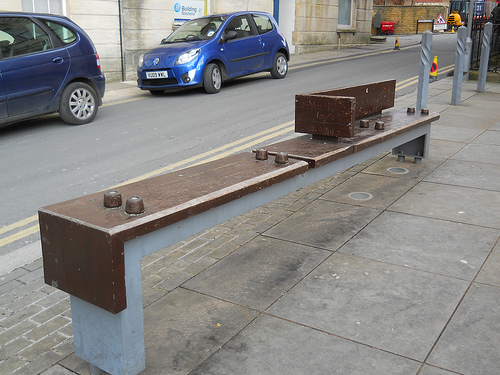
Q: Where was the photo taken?
A: It was taken at the road.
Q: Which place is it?
A: It is a road.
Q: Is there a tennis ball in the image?
A: No, there are no tennis balls.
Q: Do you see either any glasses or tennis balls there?
A: No, there are no tennis balls or glasses.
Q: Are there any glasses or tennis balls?
A: No, there are no tennis balls or glasses.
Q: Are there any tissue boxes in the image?
A: No, there are no tissue boxes.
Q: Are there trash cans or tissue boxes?
A: No, there are no tissue boxes or trash cans.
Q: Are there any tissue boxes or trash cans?
A: No, there are no tissue boxes or trash cans.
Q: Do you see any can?
A: No, there are no cans.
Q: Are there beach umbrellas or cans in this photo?
A: No, there are no cans or beach umbrellas.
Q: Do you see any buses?
A: No, there are no buses.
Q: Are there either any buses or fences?
A: No, there are no buses or fences.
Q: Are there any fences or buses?
A: No, there are no buses or fences.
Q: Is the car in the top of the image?
A: Yes, the car is in the top of the image.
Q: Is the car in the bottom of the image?
A: No, the car is in the top of the image.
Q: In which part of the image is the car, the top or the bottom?
A: The car is in the top of the image.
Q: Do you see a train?
A: No, there are no trains.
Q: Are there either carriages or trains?
A: No, there are no trains or carriages.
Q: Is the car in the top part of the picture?
A: Yes, the car is in the top of the image.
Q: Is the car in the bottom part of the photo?
A: No, the car is in the top of the image.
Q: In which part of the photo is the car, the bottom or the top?
A: The car is in the top of the image.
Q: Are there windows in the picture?
A: Yes, there is a window.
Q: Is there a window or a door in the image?
A: Yes, there is a window.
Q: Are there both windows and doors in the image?
A: Yes, there are both a window and a door.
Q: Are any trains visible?
A: No, there are no trains.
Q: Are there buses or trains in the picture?
A: No, there are no trains or buses.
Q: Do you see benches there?
A: Yes, there is a bench.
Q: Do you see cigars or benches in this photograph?
A: Yes, there is a bench.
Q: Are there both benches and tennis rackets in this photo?
A: No, there is a bench but no rackets.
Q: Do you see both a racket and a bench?
A: No, there is a bench but no rackets.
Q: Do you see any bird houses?
A: No, there are no bird houses.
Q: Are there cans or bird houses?
A: No, there are no bird houses or cans.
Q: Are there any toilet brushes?
A: No, there are no toilet brushes.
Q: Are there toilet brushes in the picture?
A: No, there are no toilet brushes.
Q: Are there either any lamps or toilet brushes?
A: No, there are no toilet brushes or lamps.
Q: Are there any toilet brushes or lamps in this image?
A: No, there are no toilet brushes or lamps.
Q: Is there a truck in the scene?
A: No, there are no trucks.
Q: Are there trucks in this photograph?
A: No, there are no trucks.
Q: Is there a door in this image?
A: Yes, there is a door.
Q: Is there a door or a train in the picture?
A: Yes, there is a door.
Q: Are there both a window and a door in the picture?
A: Yes, there are both a door and a window.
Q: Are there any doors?
A: Yes, there is a door.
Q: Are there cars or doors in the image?
A: Yes, there is a door.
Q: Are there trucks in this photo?
A: No, there are no trucks.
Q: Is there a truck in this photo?
A: No, there are no trucks.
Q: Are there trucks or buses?
A: No, there are no trucks or buses.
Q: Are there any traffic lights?
A: No, there are no traffic lights.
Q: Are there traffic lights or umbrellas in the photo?
A: No, there are no traffic lights or umbrellas.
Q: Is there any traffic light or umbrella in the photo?
A: No, there are no traffic lights or umbrellas.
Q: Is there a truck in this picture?
A: No, there are no trucks.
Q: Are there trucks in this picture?
A: No, there are no trucks.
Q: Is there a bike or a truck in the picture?
A: No, there are no trucks or bikes.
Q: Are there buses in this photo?
A: No, there are no buses.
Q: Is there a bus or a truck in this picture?
A: No, there are no buses or trucks.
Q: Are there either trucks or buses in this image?
A: No, there are no buses or trucks.